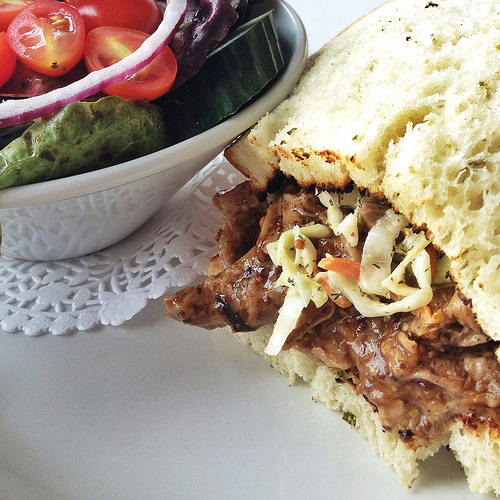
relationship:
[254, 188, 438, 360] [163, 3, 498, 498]
coleslaw on sandwich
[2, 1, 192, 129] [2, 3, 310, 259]
onion in bowl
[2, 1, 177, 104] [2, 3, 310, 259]
tomatoes are in bowl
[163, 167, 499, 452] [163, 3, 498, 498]
meat in sandwich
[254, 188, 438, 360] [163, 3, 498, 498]
coleslaw in sandwich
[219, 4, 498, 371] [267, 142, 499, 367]
bread has burnt edge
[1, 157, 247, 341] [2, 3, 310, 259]
doily under bowl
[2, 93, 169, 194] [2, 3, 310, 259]
greens are in bowl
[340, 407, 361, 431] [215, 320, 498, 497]
seeds are in bread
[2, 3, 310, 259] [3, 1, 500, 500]
bowl on surface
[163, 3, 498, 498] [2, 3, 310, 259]
sandwich next to bowl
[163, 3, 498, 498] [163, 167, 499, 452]
sandwich full of meat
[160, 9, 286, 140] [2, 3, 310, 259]
cucumber in bowl